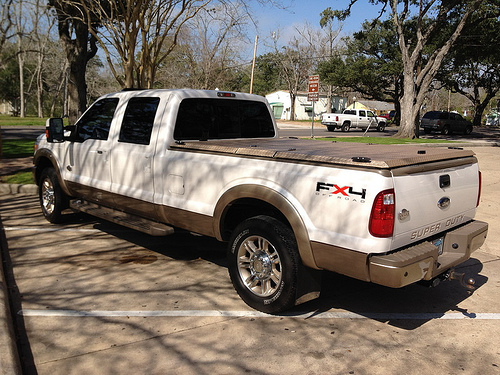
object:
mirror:
[43, 114, 68, 143]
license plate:
[427, 238, 444, 252]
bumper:
[367, 219, 490, 288]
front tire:
[38, 167, 68, 225]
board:
[67, 198, 178, 238]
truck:
[320, 106, 388, 133]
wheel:
[35, 169, 66, 224]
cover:
[164, 172, 186, 197]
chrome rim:
[238, 234, 280, 296]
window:
[67, 95, 116, 141]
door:
[62, 97, 121, 204]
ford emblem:
[438, 195, 453, 211]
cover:
[167, 137, 478, 171]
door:
[109, 92, 174, 224]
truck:
[31, 86, 490, 317]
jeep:
[422, 109, 476, 136]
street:
[0, 122, 396, 142]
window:
[171, 95, 275, 140]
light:
[367, 187, 397, 239]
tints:
[128, 105, 157, 135]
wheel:
[222, 214, 304, 317]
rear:
[374, 149, 488, 291]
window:
[117, 92, 160, 146]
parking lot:
[0, 88, 500, 374]